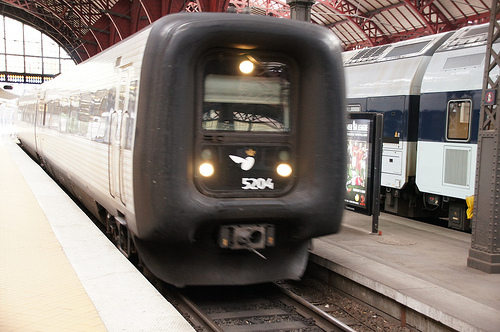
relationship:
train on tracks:
[2, 14, 347, 291] [164, 283, 354, 330]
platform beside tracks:
[3, 135, 195, 332] [164, 283, 354, 330]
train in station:
[2, 14, 347, 291] [1, 2, 499, 331]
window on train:
[202, 76, 289, 131] [2, 14, 347, 291]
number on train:
[240, 178, 273, 191] [2, 14, 347, 291]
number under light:
[240, 178, 273, 191] [199, 161, 215, 180]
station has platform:
[1, 2, 499, 331] [3, 135, 195, 332]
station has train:
[1, 2, 499, 331] [2, 14, 347, 291]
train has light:
[2, 14, 347, 291] [276, 164, 293, 178]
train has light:
[2, 14, 347, 291] [199, 161, 215, 180]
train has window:
[346, 20, 499, 241] [445, 100, 471, 142]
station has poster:
[1, 2, 499, 331] [347, 119, 372, 209]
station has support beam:
[1, 2, 499, 331] [465, 0, 500, 274]